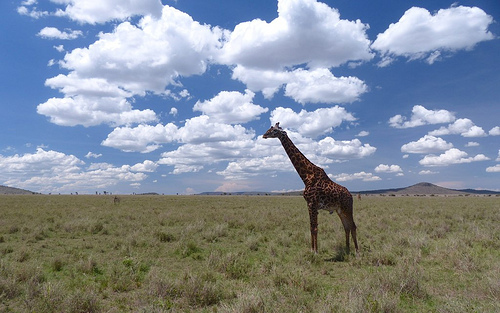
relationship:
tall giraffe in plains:
[262, 121, 359, 258] [0, 1, 265, 312]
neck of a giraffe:
[277, 134, 320, 178] [262, 121, 359, 258]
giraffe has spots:
[262, 121, 359, 258] [298, 161, 307, 169]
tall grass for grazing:
[1, 192, 303, 313] [0, 0, 499, 311]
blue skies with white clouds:
[1, 0, 498, 123] [371, 4, 493, 54]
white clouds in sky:
[371, 4, 493, 54] [1, 0, 498, 123]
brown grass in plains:
[1, 192, 303, 313] [0, 1, 265, 312]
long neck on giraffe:
[277, 134, 320, 178] [262, 121, 359, 258]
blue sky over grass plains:
[0, 0, 499, 311] [1, 192, 303, 313]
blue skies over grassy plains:
[1, 0, 498, 123] [0, 193, 497, 313]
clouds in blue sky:
[64, 7, 215, 83] [1, 0, 498, 123]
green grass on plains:
[1, 192, 303, 313] [0, 1, 265, 312]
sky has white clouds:
[1, 0, 498, 123] [371, 4, 493, 54]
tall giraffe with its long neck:
[262, 121, 359, 258] [277, 134, 320, 178]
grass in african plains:
[1, 192, 303, 313] [0, 0, 499, 311]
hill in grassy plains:
[394, 182, 465, 197] [0, 193, 497, 313]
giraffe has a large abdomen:
[262, 121, 359, 258] [303, 182, 353, 213]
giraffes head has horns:
[261, 122, 283, 140] [275, 120, 281, 129]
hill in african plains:
[1, 184, 45, 199] [0, 0, 499, 311]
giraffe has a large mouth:
[262, 121, 359, 258] [262, 132, 271, 140]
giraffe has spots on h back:
[262, 121, 359, 258] [317, 165, 353, 202]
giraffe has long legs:
[262, 121, 359, 258] [338, 204, 360, 255]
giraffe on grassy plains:
[262, 121, 359, 258] [0, 193, 497, 313]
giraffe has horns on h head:
[262, 121, 359, 258] [261, 122, 283, 140]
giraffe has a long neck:
[262, 121, 359, 258] [277, 134, 320, 178]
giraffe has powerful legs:
[262, 121, 359, 258] [338, 204, 360, 255]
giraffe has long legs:
[262, 121, 359, 258] [307, 204, 319, 255]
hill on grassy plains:
[394, 182, 465, 197] [0, 193, 497, 313]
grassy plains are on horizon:
[0, 193, 497, 313] [1, 177, 299, 210]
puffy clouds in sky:
[226, 0, 373, 69] [1, 0, 498, 123]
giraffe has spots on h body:
[262, 121, 359, 258] [303, 182, 353, 213]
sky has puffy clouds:
[1, 0, 498, 123] [226, 0, 373, 69]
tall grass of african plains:
[1, 192, 303, 313] [0, 0, 499, 311]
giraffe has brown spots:
[262, 121, 359, 258] [298, 161, 307, 169]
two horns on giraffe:
[275, 121, 280, 128] [262, 121, 359, 258]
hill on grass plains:
[394, 182, 465, 197] [1, 192, 303, 313]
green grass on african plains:
[1, 192, 303, 313] [0, 0, 499, 311]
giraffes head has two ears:
[261, 122, 283, 140] [273, 128, 278, 134]